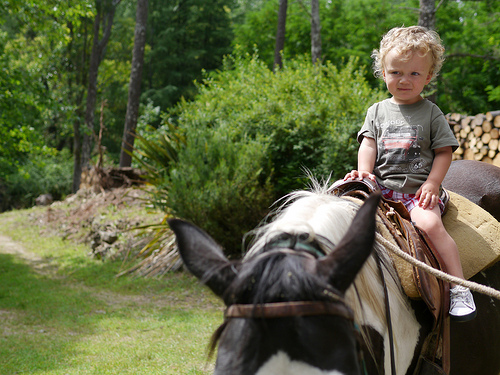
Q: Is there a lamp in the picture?
A: No, there are no lamps.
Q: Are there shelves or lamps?
A: No, there are no lamps or shelves.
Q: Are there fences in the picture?
A: No, there are no fences.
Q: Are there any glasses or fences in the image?
A: No, there are no fences or glasses.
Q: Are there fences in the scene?
A: No, there are no fences.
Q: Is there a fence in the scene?
A: No, there are no fences.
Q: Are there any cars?
A: No, there are no cars.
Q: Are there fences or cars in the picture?
A: No, there are no cars or fences.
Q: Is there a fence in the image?
A: No, there are no fences.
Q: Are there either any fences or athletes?
A: No, there are no fences or athletes.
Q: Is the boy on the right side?
A: Yes, the boy is on the right of the image.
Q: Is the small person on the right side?
A: Yes, the boy is on the right of the image.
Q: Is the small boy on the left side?
A: No, the boy is on the right of the image.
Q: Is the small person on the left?
A: No, the boy is on the right of the image.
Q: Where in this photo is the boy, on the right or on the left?
A: The boy is on the right of the image.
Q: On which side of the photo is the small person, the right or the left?
A: The boy is on the right of the image.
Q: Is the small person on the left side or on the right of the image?
A: The boy is on the right of the image.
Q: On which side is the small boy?
A: The boy is on the right of the image.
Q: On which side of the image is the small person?
A: The boy is on the right of the image.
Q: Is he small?
A: Yes, the boy is small.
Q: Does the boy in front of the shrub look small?
A: Yes, the boy is small.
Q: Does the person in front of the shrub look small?
A: Yes, the boy is small.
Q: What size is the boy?
A: The boy is small.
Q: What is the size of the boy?
A: The boy is small.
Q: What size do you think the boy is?
A: The boy is small.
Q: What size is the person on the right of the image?
A: The boy is small.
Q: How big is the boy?
A: The boy is small.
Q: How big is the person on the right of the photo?
A: The boy is small.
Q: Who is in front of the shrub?
A: The boy is in front of the shrub.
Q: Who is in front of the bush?
A: The boy is in front of the shrub.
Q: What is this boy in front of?
A: The boy is in front of the bush.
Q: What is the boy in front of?
A: The boy is in front of the bush.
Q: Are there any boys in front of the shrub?
A: Yes, there is a boy in front of the shrub.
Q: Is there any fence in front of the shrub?
A: No, there is a boy in front of the shrub.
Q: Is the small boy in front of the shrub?
A: Yes, the boy is in front of the shrub.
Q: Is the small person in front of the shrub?
A: Yes, the boy is in front of the shrub.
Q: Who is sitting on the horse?
A: The boy is sitting on the horse.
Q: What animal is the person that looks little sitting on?
A: The boy is sitting on the horse.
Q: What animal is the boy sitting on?
A: The boy is sitting on the horse.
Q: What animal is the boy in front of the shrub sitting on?
A: The boy is sitting on the horse.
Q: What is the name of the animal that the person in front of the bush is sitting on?
A: The animal is a horse.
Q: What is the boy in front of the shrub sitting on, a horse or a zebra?
A: The boy is sitting on a horse.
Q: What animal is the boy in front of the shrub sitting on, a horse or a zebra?
A: The boy is sitting on a horse.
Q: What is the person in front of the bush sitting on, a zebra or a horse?
A: The boy is sitting on a horse.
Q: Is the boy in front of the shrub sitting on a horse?
A: Yes, the boy is sitting on a horse.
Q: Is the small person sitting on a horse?
A: Yes, the boy is sitting on a horse.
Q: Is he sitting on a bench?
A: No, the boy is sitting on a horse.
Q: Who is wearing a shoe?
A: The boy is wearing a shoe.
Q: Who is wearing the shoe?
A: The boy is wearing a shoe.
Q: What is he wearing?
A: The boy is wearing a shoe.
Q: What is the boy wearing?
A: The boy is wearing a shoe.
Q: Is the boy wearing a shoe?
A: Yes, the boy is wearing a shoe.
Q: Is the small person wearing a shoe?
A: Yes, the boy is wearing a shoe.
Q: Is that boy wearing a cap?
A: No, the boy is wearing a shoe.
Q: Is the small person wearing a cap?
A: No, the boy is wearing a shoe.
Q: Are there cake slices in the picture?
A: No, there are no cake slices.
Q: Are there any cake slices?
A: No, there are no cake slices.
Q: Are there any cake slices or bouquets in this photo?
A: No, there are no cake slices or bouquets.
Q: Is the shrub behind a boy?
A: Yes, the shrub is behind a boy.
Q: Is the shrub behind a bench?
A: No, the shrub is behind a boy.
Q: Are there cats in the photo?
A: No, there are no cats.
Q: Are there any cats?
A: No, there are no cats.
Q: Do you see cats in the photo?
A: No, there are no cats.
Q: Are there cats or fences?
A: No, there are no cats or fences.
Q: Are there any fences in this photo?
A: No, there are no fences.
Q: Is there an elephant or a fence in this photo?
A: No, there are no fences or elephants.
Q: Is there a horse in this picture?
A: Yes, there is a horse.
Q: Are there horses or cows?
A: Yes, there is a horse.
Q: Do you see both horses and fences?
A: No, there is a horse but no fences.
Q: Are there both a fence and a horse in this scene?
A: No, there is a horse but no fences.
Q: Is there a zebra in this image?
A: No, there are no zebras.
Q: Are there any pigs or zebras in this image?
A: No, there are no zebras or pigs.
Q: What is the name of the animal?
A: The animal is a horse.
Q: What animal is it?
A: The animal is a horse.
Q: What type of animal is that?
A: This is a horse.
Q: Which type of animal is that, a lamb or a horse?
A: This is a horse.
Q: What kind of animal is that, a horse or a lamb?
A: This is a horse.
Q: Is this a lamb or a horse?
A: This is a horse.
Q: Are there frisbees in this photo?
A: No, there are no frisbees.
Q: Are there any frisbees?
A: No, there are no frisbees.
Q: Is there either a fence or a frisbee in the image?
A: No, there are no frisbees or fences.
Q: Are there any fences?
A: No, there are no fences.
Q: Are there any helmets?
A: No, there are no helmets.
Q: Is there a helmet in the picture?
A: No, there are no helmets.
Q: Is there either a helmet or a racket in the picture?
A: No, there are no helmets or rackets.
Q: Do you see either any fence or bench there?
A: No, there are no fences or benches.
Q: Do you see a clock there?
A: No, there are no clocks.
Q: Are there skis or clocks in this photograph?
A: No, there are no clocks or skis.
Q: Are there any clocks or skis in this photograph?
A: No, there are no clocks or skis.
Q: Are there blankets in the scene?
A: Yes, there is a blanket.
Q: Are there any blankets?
A: Yes, there is a blanket.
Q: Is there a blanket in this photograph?
A: Yes, there is a blanket.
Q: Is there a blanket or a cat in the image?
A: Yes, there is a blanket.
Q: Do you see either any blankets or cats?
A: Yes, there is a blanket.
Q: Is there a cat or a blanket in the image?
A: Yes, there is a blanket.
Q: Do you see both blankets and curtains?
A: No, there is a blanket but no curtains.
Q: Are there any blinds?
A: No, there are no blinds.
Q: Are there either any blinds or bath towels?
A: No, there are no blinds or bath towels.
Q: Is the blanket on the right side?
A: Yes, the blanket is on the right of the image.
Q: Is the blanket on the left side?
A: No, the blanket is on the right of the image.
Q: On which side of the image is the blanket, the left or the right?
A: The blanket is on the right of the image.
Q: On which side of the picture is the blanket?
A: The blanket is on the right of the image.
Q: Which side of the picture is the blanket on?
A: The blanket is on the right of the image.